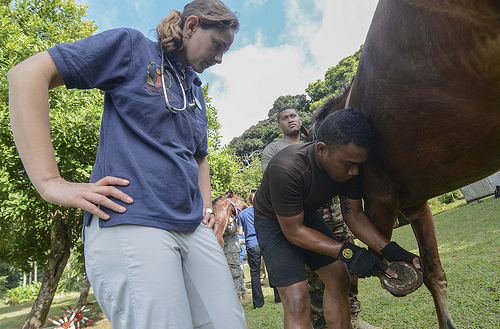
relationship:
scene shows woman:
[1, 2, 499, 326] [9, 1, 242, 328]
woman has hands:
[9, 1, 242, 328] [42, 173, 226, 241]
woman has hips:
[9, 1, 242, 328] [80, 209, 229, 266]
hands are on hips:
[42, 173, 226, 241] [80, 209, 229, 266]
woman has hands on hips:
[9, 1, 242, 328] [80, 209, 229, 266]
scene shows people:
[1, 2, 499, 326] [252, 107, 428, 328]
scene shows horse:
[1, 2, 499, 326] [319, 0, 498, 325]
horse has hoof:
[319, 0, 498, 325] [379, 254, 429, 298]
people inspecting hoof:
[252, 107, 428, 328] [379, 254, 429, 298]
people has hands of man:
[252, 107, 428, 328] [335, 242, 424, 279]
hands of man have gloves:
[335, 242, 424, 279] [338, 247, 418, 276]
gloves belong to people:
[338, 247, 418, 276] [252, 107, 428, 328]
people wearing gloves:
[252, 107, 428, 328] [338, 247, 418, 276]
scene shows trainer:
[1, 2, 499, 326] [241, 181, 265, 308]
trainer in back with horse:
[237, 189, 280, 307] [213, 191, 247, 246]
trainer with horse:
[237, 189, 280, 307] [213, 191, 247, 246]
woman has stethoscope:
[9, 1, 242, 328] [157, 34, 202, 111]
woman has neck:
[9, 1, 242, 328] [170, 44, 196, 74]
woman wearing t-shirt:
[9, 1, 242, 328] [51, 30, 204, 231]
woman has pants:
[9, 1, 242, 328] [80, 212, 250, 328]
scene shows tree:
[1, 2, 499, 326] [1, 3, 124, 329]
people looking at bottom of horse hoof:
[252, 107, 428, 328] [379, 254, 429, 298]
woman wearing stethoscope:
[9, 1, 242, 328] [157, 34, 202, 111]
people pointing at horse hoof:
[252, 107, 428, 328] [379, 254, 429, 298]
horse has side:
[319, 0, 498, 325] [323, 0, 499, 191]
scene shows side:
[1, 2, 499, 326] [323, 0, 499, 191]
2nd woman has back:
[241, 181, 265, 308] [239, 210, 256, 246]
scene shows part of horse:
[1, 2, 499, 326] [319, 0, 498, 325]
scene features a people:
[1, 2, 499, 326] [252, 107, 428, 328]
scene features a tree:
[1, 2, 499, 326] [1, 3, 124, 329]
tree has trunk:
[1, 3, 124, 329] [24, 199, 82, 327]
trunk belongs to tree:
[24, 199, 82, 327] [1, 3, 124, 329]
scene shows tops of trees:
[1, 2, 499, 326] [208, 46, 379, 190]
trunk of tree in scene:
[24, 199, 82, 327] [1, 2, 499, 326]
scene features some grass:
[1, 2, 499, 326] [448, 213, 500, 284]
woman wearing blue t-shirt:
[9, 1, 242, 328] [51, 30, 204, 231]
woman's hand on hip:
[43, 177, 135, 219] [83, 180, 141, 254]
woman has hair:
[9, 1, 242, 328] [150, 1, 240, 53]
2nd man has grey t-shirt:
[252, 107, 319, 172] [260, 136, 307, 170]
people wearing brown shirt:
[252, 107, 428, 328] [254, 142, 366, 217]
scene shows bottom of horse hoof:
[1, 2, 499, 326] [379, 254, 429, 298]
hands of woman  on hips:
[42, 173, 226, 241] [80, 209, 229, 266]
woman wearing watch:
[9, 1, 242, 328] [207, 203, 222, 217]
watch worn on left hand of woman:
[207, 203, 222, 217] [9, 1, 242, 328]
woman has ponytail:
[9, 1, 242, 328] [159, 12, 181, 54]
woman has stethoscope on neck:
[9, 1, 242, 328] [157, 34, 202, 111]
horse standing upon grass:
[319, 0, 498, 325] [448, 213, 500, 284]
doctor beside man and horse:
[9, 1, 242, 328] [255, 4, 496, 329]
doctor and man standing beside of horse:
[9, 3, 424, 329] [319, 0, 498, 325]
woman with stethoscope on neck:
[9, 1, 242, 328] [157, 34, 202, 111]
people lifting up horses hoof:
[252, 107, 428, 328] [379, 254, 429, 298]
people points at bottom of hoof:
[252, 107, 428, 328] [379, 254, 429, 298]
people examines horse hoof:
[252, 107, 428, 328] [379, 254, 429, 298]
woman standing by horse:
[9, 1, 242, 328] [319, 0, 498, 325]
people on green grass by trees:
[241, 107, 437, 328] [208, 46, 379, 190]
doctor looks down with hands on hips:
[9, 1, 242, 328] [48, 173, 225, 256]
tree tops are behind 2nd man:
[208, 46, 379, 190] [264, 108, 305, 169]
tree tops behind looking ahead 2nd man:
[208, 46, 379, 190] [264, 108, 305, 169]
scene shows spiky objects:
[1, 2, 499, 326] [47, 303, 97, 327]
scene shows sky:
[1, 2, 499, 326] [90, 0, 360, 149]